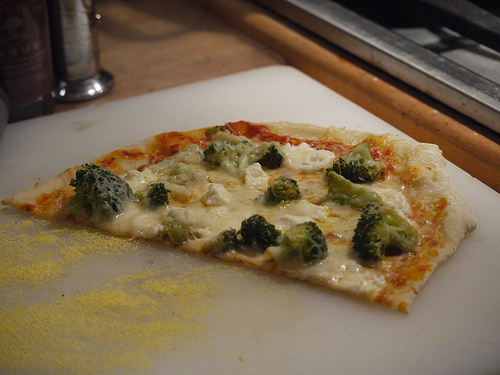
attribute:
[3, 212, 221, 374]
seasonings — yellow, scattered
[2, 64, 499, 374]
plate — white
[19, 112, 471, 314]
pizza — halved, vegetarian, cooked, baked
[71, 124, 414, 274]
broccoli — cooked, green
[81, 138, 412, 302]
cheese topping — mozzarella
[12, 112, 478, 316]
crust — thin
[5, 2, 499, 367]
table — faded, wood, wooden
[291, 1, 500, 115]
bar — metal, stove top, brown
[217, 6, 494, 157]
bar — wood, raised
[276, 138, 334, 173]
cheese — lumpy, unmelted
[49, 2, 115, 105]
salt shaker — silver